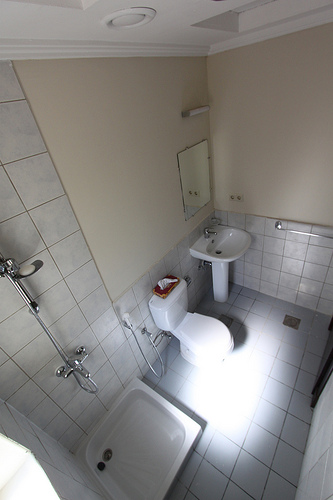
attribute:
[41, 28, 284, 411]
bathroom — here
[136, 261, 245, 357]
toilet — here, white, closed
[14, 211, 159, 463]
shower — here, clean, small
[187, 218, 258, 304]
sink — here, white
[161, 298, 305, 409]
floor — hwite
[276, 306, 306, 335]
drain — here, open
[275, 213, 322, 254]
towel rack — here, empty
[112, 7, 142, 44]
vent — here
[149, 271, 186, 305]
tissue box — multicolored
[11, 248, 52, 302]
shower head — here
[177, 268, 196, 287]
toilet paper dispens — empty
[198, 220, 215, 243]
faucet — silver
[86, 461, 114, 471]
soap — here